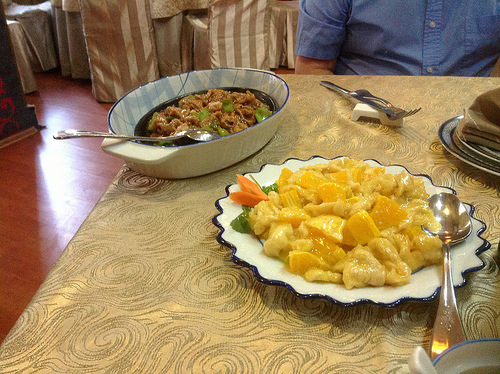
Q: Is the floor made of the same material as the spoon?
A: No, the floor is made of wood and the spoon is made of metal.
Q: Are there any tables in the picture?
A: Yes, there is a table.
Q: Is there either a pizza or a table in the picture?
A: Yes, there is a table.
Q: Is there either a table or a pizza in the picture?
A: Yes, there is a table.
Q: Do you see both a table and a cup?
A: No, there is a table but no cups.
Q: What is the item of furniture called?
A: The piece of furniture is a table.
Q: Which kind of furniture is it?
A: The piece of furniture is a table.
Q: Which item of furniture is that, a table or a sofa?
A: That is a table.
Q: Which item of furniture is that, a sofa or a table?
A: That is a table.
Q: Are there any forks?
A: Yes, there is a fork.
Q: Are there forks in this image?
A: Yes, there is a fork.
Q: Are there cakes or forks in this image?
A: Yes, there is a fork.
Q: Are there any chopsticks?
A: No, there are no chopsticks.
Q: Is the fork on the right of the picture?
A: Yes, the fork is on the right of the image.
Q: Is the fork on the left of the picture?
A: No, the fork is on the right of the image.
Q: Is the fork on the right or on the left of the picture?
A: The fork is on the right of the image.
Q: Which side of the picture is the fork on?
A: The fork is on the right of the image.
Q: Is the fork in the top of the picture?
A: Yes, the fork is in the top of the image.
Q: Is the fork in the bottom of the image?
A: No, the fork is in the top of the image.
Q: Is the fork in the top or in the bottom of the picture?
A: The fork is in the top of the image.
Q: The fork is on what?
A: The fork is on the table.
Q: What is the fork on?
A: The fork is on the table.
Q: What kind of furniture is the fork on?
A: The fork is on the table.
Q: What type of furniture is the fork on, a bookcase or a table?
A: The fork is on a table.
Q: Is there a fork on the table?
A: Yes, there is a fork on the table.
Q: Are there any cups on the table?
A: No, there is a fork on the table.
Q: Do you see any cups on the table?
A: No, there is a fork on the table.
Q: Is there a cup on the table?
A: No, there is a fork on the table.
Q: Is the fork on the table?
A: Yes, the fork is on the table.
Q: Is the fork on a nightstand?
A: No, the fork is on the table.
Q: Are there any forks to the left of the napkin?
A: Yes, there is a fork to the left of the napkin.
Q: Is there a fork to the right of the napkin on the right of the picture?
A: No, the fork is to the left of the napkin.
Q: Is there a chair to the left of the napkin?
A: No, there is a fork to the left of the napkin.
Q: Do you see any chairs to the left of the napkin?
A: No, there is a fork to the left of the napkin.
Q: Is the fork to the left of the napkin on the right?
A: Yes, the fork is to the left of the napkin.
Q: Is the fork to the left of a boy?
A: No, the fork is to the left of the napkin.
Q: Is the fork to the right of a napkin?
A: No, the fork is to the left of a napkin.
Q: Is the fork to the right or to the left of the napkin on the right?
A: The fork is to the left of the napkin.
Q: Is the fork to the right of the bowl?
A: Yes, the fork is to the right of the bowl.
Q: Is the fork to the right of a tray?
A: No, the fork is to the right of the bowl.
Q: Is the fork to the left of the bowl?
A: No, the fork is to the right of the bowl.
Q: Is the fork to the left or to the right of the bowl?
A: The fork is to the right of the bowl.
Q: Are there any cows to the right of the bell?
A: No, there is a fork to the right of the bell.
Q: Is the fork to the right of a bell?
A: Yes, the fork is to the right of a bell.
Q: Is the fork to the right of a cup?
A: No, the fork is to the right of a bell.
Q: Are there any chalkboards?
A: No, there are no chalkboards.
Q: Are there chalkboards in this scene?
A: No, there are no chalkboards.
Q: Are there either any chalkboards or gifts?
A: No, there are no chalkboards or gifts.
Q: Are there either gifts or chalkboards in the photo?
A: No, there are no chalkboards or gifts.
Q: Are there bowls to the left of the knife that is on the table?
A: Yes, there is a bowl to the left of the knife.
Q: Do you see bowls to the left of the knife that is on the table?
A: Yes, there is a bowl to the left of the knife.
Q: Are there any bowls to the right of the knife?
A: No, the bowl is to the left of the knife.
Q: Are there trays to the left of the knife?
A: No, there is a bowl to the left of the knife.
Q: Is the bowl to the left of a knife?
A: Yes, the bowl is to the left of a knife.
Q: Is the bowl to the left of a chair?
A: No, the bowl is to the left of a knife.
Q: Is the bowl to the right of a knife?
A: No, the bowl is to the left of a knife.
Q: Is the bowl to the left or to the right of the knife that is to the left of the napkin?
A: The bowl is to the left of the knife.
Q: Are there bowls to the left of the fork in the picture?
A: Yes, there is a bowl to the left of the fork.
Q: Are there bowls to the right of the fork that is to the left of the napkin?
A: No, the bowl is to the left of the fork.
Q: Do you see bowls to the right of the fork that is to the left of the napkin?
A: No, the bowl is to the left of the fork.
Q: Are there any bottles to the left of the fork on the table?
A: No, there is a bowl to the left of the fork.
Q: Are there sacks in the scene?
A: No, there are no sacks.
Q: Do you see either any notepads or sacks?
A: No, there are no sacks or notepads.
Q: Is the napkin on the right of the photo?
A: Yes, the napkin is on the right of the image.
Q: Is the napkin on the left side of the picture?
A: No, the napkin is on the right of the image.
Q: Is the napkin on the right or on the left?
A: The napkin is on the right of the image.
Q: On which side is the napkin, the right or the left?
A: The napkin is on the right of the image.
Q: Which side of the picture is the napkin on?
A: The napkin is on the right of the image.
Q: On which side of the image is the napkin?
A: The napkin is on the right of the image.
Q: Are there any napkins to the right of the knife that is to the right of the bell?
A: Yes, there is a napkin to the right of the knife.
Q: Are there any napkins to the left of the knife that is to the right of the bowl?
A: No, the napkin is to the right of the knife.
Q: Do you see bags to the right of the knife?
A: No, there is a napkin to the right of the knife.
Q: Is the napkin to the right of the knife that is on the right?
A: Yes, the napkin is to the right of the knife.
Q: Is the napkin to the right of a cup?
A: No, the napkin is to the right of the knife.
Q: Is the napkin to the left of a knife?
A: No, the napkin is to the right of a knife.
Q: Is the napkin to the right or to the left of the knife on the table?
A: The napkin is to the right of the knife.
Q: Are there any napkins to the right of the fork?
A: Yes, there is a napkin to the right of the fork.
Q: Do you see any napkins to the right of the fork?
A: Yes, there is a napkin to the right of the fork.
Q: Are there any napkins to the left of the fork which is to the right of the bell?
A: No, the napkin is to the right of the fork.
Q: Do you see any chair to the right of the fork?
A: No, there is a napkin to the right of the fork.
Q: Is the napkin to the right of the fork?
A: Yes, the napkin is to the right of the fork.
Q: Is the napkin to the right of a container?
A: No, the napkin is to the right of the fork.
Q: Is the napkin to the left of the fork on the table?
A: No, the napkin is to the right of the fork.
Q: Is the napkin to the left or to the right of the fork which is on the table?
A: The napkin is to the right of the fork.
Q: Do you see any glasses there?
A: No, there are no glasses.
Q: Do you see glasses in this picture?
A: No, there are no glasses.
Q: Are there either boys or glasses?
A: No, there are no glasses or boys.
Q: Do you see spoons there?
A: Yes, there is a spoon.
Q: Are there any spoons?
A: Yes, there is a spoon.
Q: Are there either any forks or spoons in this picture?
A: Yes, there is a spoon.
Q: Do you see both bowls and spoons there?
A: Yes, there are both a spoon and a bowl.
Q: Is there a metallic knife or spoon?
A: Yes, there is a metal spoon.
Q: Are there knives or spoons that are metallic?
A: Yes, the spoon is metallic.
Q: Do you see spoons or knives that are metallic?
A: Yes, the spoon is metallic.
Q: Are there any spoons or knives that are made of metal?
A: Yes, the spoon is made of metal.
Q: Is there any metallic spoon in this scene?
A: Yes, there is a metal spoon.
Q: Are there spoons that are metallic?
A: Yes, there is a spoon that is metallic.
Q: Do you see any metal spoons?
A: Yes, there is a spoon that is made of metal.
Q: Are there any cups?
A: No, there are no cups.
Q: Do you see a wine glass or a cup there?
A: No, there are no cups or wine glasses.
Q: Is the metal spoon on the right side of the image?
A: Yes, the spoon is on the right of the image.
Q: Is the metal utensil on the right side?
A: Yes, the spoon is on the right of the image.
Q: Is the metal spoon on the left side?
A: No, the spoon is on the right of the image.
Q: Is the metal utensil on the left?
A: No, the spoon is on the right of the image.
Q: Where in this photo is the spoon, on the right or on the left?
A: The spoon is on the right of the image.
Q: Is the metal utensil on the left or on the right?
A: The spoon is on the right of the image.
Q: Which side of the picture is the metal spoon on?
A: The spoon is on the right of the image.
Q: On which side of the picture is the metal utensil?
A: The spoon is on the right of the image.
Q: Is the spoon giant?
A: Yes, the spoon is giant.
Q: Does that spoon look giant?
A: Yes, the spoon is giant.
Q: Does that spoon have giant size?
A: Yes, the spoon is giant.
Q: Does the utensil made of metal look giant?
A: Yes, the spoon is giant.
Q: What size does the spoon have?
A: The spoon has giant size.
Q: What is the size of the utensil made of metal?
A: The spoon is giant.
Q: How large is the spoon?
A: The spoon is giant.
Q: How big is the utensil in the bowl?
A: The spoon is giant.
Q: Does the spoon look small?
A: No, the spoon is giant.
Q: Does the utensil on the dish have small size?
A: No, the spoon is giant.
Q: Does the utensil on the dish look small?
A: No, the spoon is giant.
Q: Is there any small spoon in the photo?
A: No, there is a spoon but it is giant.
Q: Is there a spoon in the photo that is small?
A: No, there is a spoon but it is giant.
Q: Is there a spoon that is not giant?
A: No, there is a spoon but it is giant.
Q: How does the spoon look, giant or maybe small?
A: The spoon is giant.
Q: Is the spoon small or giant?
A: The spoon is giant.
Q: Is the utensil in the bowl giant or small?
A: The spoon is giant.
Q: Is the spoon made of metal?
A: Yes, the spoon is made of metal.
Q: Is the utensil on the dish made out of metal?
A: Yes, the spoon is made of metal.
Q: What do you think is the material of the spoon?
A: The spoon is made of metal.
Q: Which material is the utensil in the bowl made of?
A: The spoon is made of metal.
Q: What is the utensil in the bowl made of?
A: The spoon is made of metal.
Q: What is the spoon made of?
A: The spoon is made of metal.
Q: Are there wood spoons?
A: No, there is a spoon but it is made of metal.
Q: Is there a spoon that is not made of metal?
A: No, there is a spoon but it is made of metal.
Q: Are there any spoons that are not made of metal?
A: No, there is a spoon but it is made of metal.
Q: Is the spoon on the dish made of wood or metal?
A: The spoon is made of metal.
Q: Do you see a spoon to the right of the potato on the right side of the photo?
A: Yes, there is a spoon to the right of the potato.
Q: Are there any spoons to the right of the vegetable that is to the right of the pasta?
A: Yes, there is a spoon to the right of the potato.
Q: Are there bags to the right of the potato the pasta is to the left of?
A: No, there is a spoon to the right of the potato.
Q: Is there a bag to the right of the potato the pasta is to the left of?
A: No, there is a spoon to the right of the potato.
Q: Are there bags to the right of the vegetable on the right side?
A: No, there is a spoon to the right of the potato.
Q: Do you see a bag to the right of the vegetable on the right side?
A: No, there is a spoon to the right of the potato.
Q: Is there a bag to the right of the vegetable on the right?
A: No, there is a spoon to the right of the potato.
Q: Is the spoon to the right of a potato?
A: Yes, the spoon is to the right of a potato.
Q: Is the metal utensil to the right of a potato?
A: Yes, the spoon is to the right of a potato.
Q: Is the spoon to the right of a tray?
A: No, the spoon is to the right of a potato.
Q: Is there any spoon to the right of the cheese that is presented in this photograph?
A: Yes, there is a spoon to the right of the cheese.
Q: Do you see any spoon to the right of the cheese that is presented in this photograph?
A: Yes, there is a spoon to the right of the cheese.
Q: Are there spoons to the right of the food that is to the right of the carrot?
A: Yes, there is a spoon to the right of the cheese.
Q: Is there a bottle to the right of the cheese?
A: No, there is a spoon to the right of the cheese.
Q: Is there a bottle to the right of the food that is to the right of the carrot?
A: No, there is a spoon to the right of the cheese.